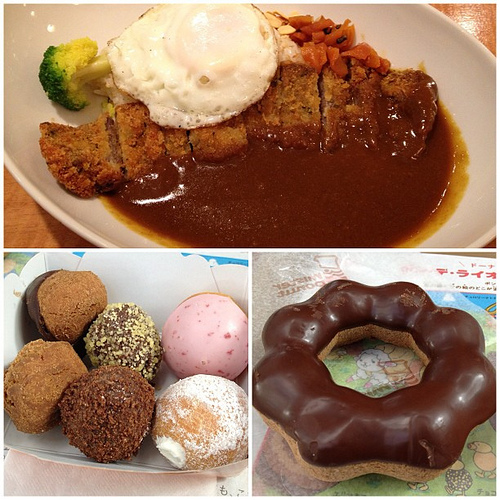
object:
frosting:
[252, 279, 497, 469]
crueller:
[252, 279, 496, 482]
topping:
[153, 374, 248, 468]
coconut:
[57, 364, 156, 464]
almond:
[83, 301, 166, 383]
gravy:
[99, 60, 469, 248]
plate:
[3, 3, 496, 249]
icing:
[160, 294, 248, 380]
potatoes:
[106, 3, 279, 130]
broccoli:
[38, 35, 111, 112]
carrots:
[341, 41, 380, 68]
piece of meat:
[37, 113, 127, 200]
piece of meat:
[116, 102, 166, 182]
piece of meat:
[189, 114, 249, 161]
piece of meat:
[318, 56, 378, 154]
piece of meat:
[380, 68, 439, 160]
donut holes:
[3, 270, 248, 471]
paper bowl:
[2, 251, 248, 478]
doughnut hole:
[149, 372, 248, 470]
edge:
[1, 250, 248, 280]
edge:
[295, 445, 458, 485]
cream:
[155, 435, 187, 470]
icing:
[23, 269, 61, 341]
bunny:
[345, 347, 398, 397]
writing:
[436, 262, 497, 279]